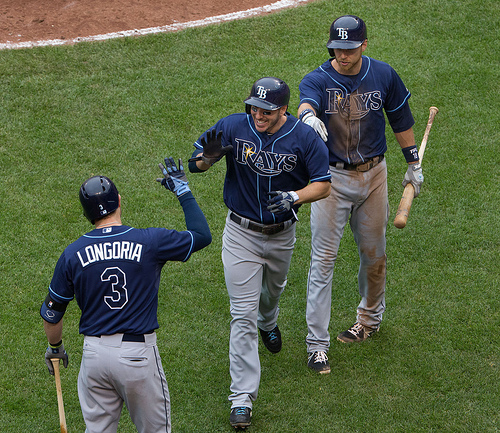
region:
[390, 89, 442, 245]
Dirty baseball bat in a player's hand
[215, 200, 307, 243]
Dark brown belt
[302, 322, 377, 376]
Navy shoes with white shoelaces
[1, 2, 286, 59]
White chalk border around baseball field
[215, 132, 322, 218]
Tampa Bay Rays jersey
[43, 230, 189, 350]
Tampa Bay Rays jersey, printed with "Longoria 3"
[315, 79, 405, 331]
Baseball uniform covered in brown dirt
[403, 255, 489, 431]
Green baseball field grass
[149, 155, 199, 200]
Blue, black, and gray glove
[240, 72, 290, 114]
Tampa Bay baseball hard hat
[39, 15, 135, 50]
white line on field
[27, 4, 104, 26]
red clay on the field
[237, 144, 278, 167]
yellow star on the gray shirt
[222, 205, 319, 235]
black belt in the belt holder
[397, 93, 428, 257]
wooden bat in man's hand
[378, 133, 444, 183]
black wrist band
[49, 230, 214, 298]
name on back of gray jersey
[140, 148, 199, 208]
two tone blue gloves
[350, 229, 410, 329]
dirt on man's pants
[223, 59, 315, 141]
shiny blue helmet on player's head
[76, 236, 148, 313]
number three on Longoria's jersey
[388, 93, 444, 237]
player holding baseball bat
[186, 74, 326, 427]
blue and white baseball uniform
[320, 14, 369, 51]
dark blue hard hat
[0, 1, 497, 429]
green baseball field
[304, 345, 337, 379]
blue shoes with white laces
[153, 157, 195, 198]
dark blue and light blue baseball gloves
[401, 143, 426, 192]
gray and black baseball gloves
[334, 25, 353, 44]
letters T and B on baseball hat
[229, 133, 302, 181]
team name is rays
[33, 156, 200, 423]
baseball player holding baseball bat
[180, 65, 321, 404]
smiling baseball player high fiving another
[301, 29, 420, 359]
baseball player with dirty pants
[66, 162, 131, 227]
batting helmet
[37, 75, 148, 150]
green grass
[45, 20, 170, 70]
white line on baseball field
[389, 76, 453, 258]
brown baseball bat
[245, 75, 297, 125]
batting helmet with TB on the front in white letters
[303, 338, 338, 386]
baseball shoe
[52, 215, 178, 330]
jersey with number 3 on back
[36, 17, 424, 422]
three baseball players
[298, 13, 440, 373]
a baseball player holding a bat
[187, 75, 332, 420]
A smiling baseball player.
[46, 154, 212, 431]
the back of a baseball player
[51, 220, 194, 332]
the number three on a blue jersey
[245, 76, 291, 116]
a baseball helmet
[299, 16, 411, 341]
a man wearing a dirty uniform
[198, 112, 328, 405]
a blue and gray uniform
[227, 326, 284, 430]
a pair of cleats with blue shoelaces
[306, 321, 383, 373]
a pair of shoes with white shoelaces